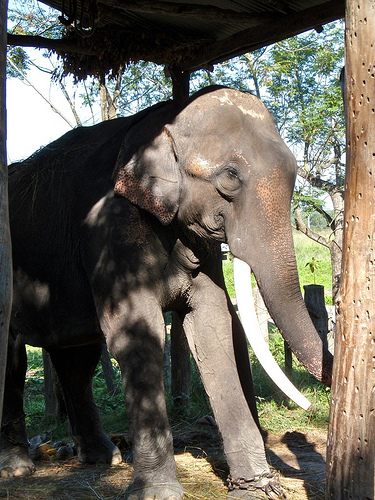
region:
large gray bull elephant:
[4, 84, 312, 494]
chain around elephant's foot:
[224, 468, 284, 498]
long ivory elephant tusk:
[231, 255, 312, 409]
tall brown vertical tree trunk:
[322, 0, 374, 496]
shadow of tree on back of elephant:
[6, 83, 228, 485]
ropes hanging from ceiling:
[55, 1, 100, 38]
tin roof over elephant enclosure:
[38, 0, 360, 53]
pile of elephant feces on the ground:
[27, 430, 74, 464]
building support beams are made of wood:
[0, 0, 373, 497]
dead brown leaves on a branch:
[8, 17, 215, 85]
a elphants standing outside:
[65, 33, 359, 420]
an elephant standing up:
[76, 90, 337, 431]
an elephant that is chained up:
[39, 87, 374, 464]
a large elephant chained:
[28, 95, 332, 489]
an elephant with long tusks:
[150, 77, 323, 350]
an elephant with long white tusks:
[158, 172, 361, 425]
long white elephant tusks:
[230, 231, 359, 451]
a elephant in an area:
[61, 186, 330, 490]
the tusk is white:
[200, 237, 310, 413]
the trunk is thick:
[244, 198, 331, 382]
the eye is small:
[210, 148, 243, 188]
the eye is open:
[214, 160, 248, 202]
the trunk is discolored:
[243, 126, 303, 333]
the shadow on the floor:
[266, 412, 322, 488]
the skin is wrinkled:
[172, 191, 230, 251]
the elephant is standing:
[3, 68, 316, 417]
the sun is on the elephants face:
[159, 100, 283, 200]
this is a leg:
[95, 223, 182, 499]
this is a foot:
[125, 465, 181, 495]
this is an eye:
[211, 154, 244, 193]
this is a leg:
[60, 347, 120, 462]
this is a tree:
[274, 31, 339, 301]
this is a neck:
[163, 203, 224, 283]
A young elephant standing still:
[5, 87, 333, 498]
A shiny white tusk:
[231, 257, 314, 415]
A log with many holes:
[344, 3, 371, 484]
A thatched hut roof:
[38, 2, 339, 72]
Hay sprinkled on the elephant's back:
[10, 133, 95, 220]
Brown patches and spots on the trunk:
[257, 165, 289, 282]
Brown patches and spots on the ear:
[109, 160, 176, 222]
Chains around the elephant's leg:
[0, 412, 27, 449]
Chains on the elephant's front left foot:
[225, 470, 285, 494]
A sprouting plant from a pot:
[303, 255, 323, 310]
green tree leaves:
[273, 35, 315, 71]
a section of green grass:
[245, 370, 330, 424]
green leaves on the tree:
[322, 75, 335, 123]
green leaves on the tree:
[295, 132, 308, 150]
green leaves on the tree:
[305, 192, 323, 210]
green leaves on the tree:
[259, 40, 287, 86]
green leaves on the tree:
[216, 65, 233, 78]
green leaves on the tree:
[150, 74, 167, 102]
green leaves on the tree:
[134, 77, 150, 101]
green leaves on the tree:
[27, 13, 47, 29]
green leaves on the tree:
[11, 50, 35, 82]